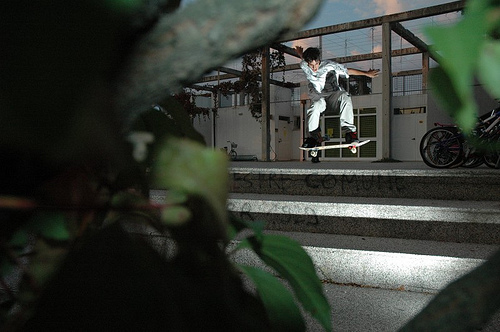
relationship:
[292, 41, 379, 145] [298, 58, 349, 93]
boy wearing shirt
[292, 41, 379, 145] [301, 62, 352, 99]
boy wearing shirt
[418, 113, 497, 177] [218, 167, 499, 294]
bikes parked near gray stairs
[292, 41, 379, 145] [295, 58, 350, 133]
boy on clothes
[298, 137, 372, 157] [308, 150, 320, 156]
board has wheels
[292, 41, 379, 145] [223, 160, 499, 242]
boy on steps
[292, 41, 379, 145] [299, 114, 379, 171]
boy wearing shoes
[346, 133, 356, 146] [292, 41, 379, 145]
shoe on boy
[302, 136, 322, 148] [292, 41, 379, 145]
shoe on boy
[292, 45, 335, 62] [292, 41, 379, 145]
hair on boy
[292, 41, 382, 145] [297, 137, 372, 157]
boy on skateboard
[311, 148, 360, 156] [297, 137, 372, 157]
wheels of a skateboard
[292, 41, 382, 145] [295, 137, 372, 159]
boy on a skateboard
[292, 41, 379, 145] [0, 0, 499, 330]
boy skateboarding outside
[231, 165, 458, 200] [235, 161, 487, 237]
graffiti on steps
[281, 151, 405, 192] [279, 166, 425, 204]
writing says commune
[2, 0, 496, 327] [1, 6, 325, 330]
picture taken from behind plant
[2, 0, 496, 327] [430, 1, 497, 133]
picture taken from behind plant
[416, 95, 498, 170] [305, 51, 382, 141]
motorcycle near man